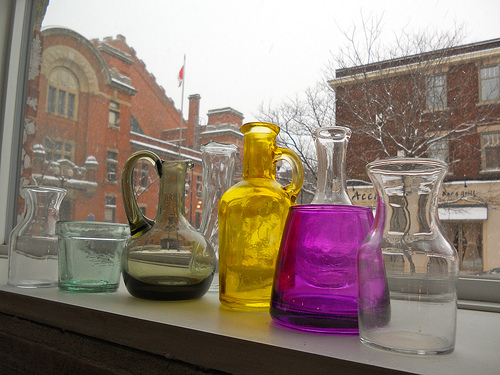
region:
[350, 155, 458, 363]
clear vase on shelving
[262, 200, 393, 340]
purple vase on table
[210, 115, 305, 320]
yellow vase with handle on table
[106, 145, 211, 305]
green vase with handle on shelving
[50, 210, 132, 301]
aqua glass on table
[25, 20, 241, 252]
old red and white brick building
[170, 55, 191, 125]
red and white flag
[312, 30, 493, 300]
old red brick building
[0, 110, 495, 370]
glassware on table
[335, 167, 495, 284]
storefront of building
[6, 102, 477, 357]
Colorful bottles window sill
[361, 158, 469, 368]
Clear decanter style vase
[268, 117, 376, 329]
Clear vase inside purple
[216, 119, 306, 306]
Amber glass handled pitcher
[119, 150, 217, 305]
Unique shape green pitcher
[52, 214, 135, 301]
Light green glass planter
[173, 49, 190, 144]
Flag hangs flag pole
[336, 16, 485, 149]
Bare tree denotes cold weather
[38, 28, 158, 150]
Red brick large townhall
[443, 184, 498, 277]
Downtown shop curtained window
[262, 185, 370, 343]
the glass is purple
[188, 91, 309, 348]
the bottle is yellow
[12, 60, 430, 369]
the bottles are on the counter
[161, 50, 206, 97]
the flag is rred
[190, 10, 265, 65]
the sky is white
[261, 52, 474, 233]
the trees are bare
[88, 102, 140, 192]
the wall is red orange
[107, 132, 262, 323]
the bottle is green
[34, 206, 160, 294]
the glass is green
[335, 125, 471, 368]
the jar is transparent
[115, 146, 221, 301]
A grey glass bottle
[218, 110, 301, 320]
A yellow glass bottle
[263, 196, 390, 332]
A purple glass jar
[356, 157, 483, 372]
A clear glass carafe.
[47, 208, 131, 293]
A clear glass jar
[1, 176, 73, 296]
A clear glass carafe.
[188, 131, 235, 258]
A clear glass vase.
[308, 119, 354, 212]
A clear glass vase.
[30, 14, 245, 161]
A red brick building.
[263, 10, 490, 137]
A barren tree in winter.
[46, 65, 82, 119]
window with arch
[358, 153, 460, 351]
dirty glass carafe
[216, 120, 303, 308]
yellow glass with handle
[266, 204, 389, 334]
purple glass on windowsill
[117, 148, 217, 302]
olive green glass vase with handle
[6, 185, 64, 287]
smaller dirty clear glass carafe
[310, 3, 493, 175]
bare tree branches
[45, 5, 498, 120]
cloudy, overcast sky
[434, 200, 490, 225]
awning over store window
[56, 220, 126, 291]
light green glass flower pot or candle holder